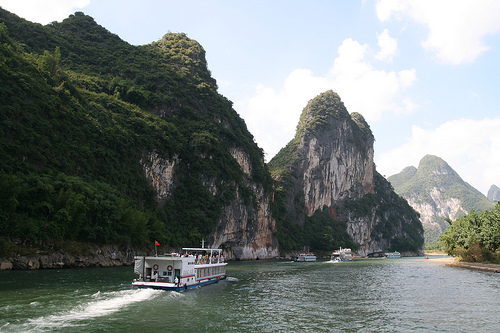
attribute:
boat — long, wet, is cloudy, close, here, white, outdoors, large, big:
[141, 217, 231, 297]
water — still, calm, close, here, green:
[322, 264, 400, 312]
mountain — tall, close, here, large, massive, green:
[101, 44, 292, 222]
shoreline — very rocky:
[5, 239, 292, 279]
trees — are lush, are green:
[424, 190, 497, 266]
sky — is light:
[0, 3, 498, 163]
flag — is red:
[156, 234, 162, 247]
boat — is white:
[133, 242, 235, 291]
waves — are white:
[0, 281, 174, 329]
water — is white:
[40, 276, 164, 326]